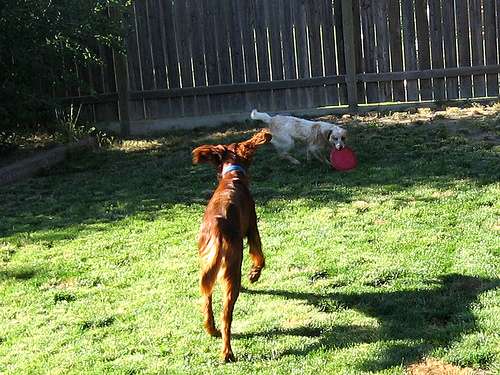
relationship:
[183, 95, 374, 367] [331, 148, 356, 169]
two dogs playing with frisbee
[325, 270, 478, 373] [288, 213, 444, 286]
shadow on grass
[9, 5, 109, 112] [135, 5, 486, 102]
tree growing next to fence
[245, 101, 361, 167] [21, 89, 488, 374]
dog in yard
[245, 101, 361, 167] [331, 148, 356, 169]
dog holding frisbee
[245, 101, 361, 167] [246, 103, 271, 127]
dog has tail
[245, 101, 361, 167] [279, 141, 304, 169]
dog has hind leg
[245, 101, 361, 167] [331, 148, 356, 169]
dog has frisbee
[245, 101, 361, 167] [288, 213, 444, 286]
dog in grass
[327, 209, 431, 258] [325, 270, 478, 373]
ground has a shadow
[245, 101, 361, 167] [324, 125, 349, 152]
dog has a head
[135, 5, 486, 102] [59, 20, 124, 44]
fence in background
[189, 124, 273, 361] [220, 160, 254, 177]
dog has collar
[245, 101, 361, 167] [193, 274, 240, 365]
dog has back legs